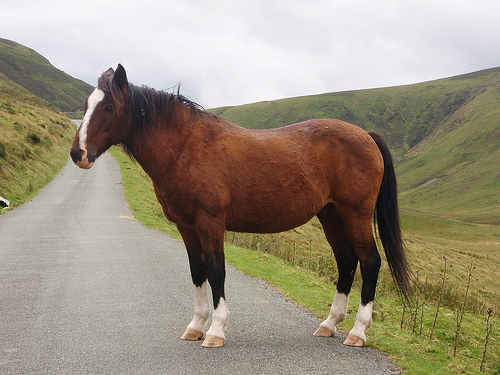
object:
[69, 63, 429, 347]
horse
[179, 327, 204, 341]
hoof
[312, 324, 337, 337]
hoof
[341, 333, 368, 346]
hoof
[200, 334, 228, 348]
hoof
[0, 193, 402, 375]
concrete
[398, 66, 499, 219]
grass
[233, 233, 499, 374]
fence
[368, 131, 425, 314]
tail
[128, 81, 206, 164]
mane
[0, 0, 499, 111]
sky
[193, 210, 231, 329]
leg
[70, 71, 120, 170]
face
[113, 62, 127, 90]
ear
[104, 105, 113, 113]
eye